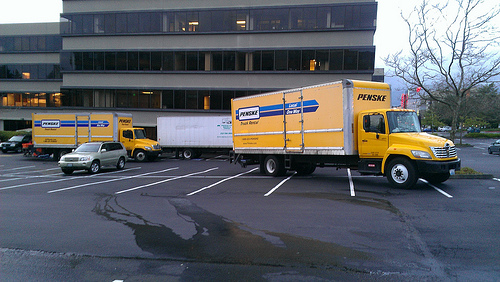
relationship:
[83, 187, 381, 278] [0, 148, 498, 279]
water on ground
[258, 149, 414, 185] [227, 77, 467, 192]
wheels on truck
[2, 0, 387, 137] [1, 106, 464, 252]
building around area